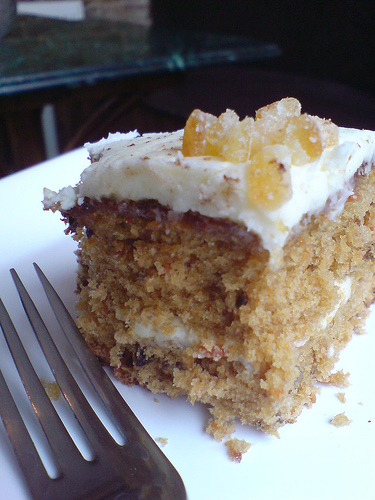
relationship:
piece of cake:
[41, 184, 86, 225] [78, 116, 374, 387]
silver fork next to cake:
[104, 465, 151, 488] [78, 116, 374, 387]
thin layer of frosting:
[177, 330, 191, 346] [309, 169, 334, 192]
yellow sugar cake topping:
[292, 120, 311, 137] [246, 160, 289, 209]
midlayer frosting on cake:
[339, 277, 358, 297] [78, 116, 374, 387]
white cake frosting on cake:
[161, 172, 195, 197] [78, 116, 374, 387]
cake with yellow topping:
[78, 116, 374, 387] [246, 160, 289, 209]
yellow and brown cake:
[292, 120, 311, 137] [78, 116, 374, 387]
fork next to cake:
[2, 261, 75, 483] [78, 116, 374, 387]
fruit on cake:
[189, 117, 224, 152] [78, 116, 374, 387]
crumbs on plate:
[202, 418, 249, 459] [266, 449, 354, 496]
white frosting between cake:
[161, 172, 195, 197] [78, 116, 374, 387]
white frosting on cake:
[161, 172, 195, 197] [78, 116, 374, 387]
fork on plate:
[2, 261, 75, 483] [266, 449, 354, 496]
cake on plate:
[78, 116, 374, 387] [266, 449, 354, 496]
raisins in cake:
[129, 346, 152, 367] [78, 116, 374, 387]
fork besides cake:
[2, 261, 75, 483] [78, 116, 374, 387]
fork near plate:
[2, 261, 75, 483] [266, 449, 354, 496]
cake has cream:
[78, 116, 374, 387] [347, 129, 374, 154]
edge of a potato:
[292, 95, 302, 108] [230, 131, 262, 152]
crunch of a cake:
[288, 121, 315, 142] [78, 116, 374, 387]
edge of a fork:
[27, 261, 46, 277] [2, 261, 75, 483]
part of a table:
[234, 36, 259, 51] [47, 23, 132, 52]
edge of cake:
[92, 130, 141, 153] [78, 116, 374, 387]